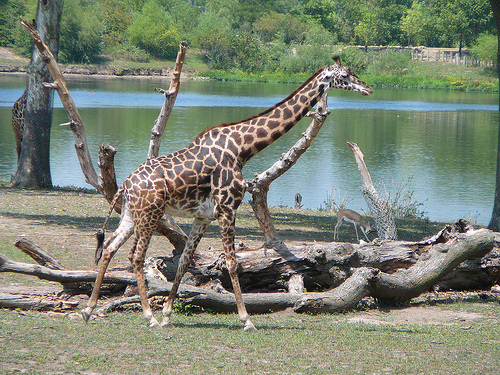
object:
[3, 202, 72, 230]
ground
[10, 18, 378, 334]
animal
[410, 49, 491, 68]
bridge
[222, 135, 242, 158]
spots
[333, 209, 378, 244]
animal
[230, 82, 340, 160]
neck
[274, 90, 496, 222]
water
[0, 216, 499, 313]
log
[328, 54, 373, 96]
head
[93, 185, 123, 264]
giraffe`s tail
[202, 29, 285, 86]
tree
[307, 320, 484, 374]
ground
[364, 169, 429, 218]
fencing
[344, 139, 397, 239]
tree limb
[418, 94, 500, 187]
water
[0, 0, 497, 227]
background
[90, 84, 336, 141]
water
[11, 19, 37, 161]
giraffe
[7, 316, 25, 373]
grass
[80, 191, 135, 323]
legs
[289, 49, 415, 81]
flowers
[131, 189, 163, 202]
spots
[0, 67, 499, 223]
lake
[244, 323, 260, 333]
hoof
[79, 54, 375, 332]
giraffe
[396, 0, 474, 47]
trees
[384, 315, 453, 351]
ground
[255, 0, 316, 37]
trees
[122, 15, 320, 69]
shrubs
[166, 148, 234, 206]
spots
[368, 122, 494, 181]
reflection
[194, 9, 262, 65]
distance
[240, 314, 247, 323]
part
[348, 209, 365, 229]
part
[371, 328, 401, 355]
part